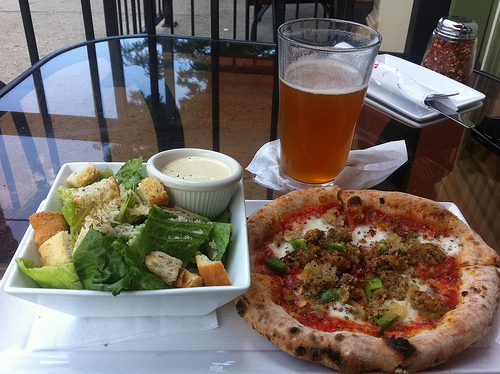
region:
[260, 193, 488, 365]
a pizza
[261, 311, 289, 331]
the crust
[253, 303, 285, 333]
the crust is brown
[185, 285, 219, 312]
a white bowl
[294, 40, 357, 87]
a clear glass on the table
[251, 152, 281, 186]
a white napkin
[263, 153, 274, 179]
the napkin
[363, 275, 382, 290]
green peppers on the pizza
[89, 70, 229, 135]
a shadow on the table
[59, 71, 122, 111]
a glass table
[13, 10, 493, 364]
A meal ready to be eaten.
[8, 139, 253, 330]
A square white bowl.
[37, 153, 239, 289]
Green salad in a bowl.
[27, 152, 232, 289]
Big sized croutons on a salad.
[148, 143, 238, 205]
A small round bowl.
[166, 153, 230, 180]
White dressing in a bowl.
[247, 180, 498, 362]
A small thick crust pizza.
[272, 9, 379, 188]
A large glass of beverage.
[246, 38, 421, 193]
White napkin under the glass.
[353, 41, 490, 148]
Silverware wrapped in a napkin.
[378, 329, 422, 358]
the crust is burnt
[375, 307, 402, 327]
the pepper is green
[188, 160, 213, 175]
the sauce is cream color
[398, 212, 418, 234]
the sauce is red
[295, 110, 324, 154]
the liquid is amber color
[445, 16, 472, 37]
the lid is silver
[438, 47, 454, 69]
the seeds are red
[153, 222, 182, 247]
the lettuce is green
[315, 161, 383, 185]
the glass is on the napkin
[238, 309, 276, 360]
the pizza is on the plate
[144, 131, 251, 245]
the dressing is white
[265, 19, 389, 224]
iced tea in a glass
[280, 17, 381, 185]
a glass of beer on a table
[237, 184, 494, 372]
a small pizza on a table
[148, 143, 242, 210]
white sauce in a white cup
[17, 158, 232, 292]
a Cesar salad in a white plate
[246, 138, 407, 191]
a white crumpled napkin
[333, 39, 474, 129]
utensils in a rolled up napkin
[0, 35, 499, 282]
a glass table with black borders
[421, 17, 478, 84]
a red pepper shaker on a table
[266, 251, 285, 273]
a bit of green pepper on a pizza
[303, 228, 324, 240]
hamburger meat on a pizza